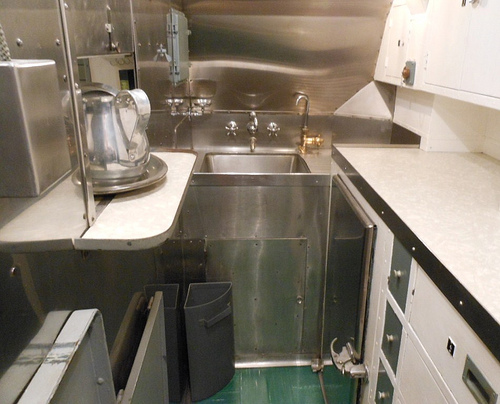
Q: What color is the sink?
A: Silver.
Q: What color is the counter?
A: White.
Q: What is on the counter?
A: Nothing.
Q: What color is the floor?
A: Green.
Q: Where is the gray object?
A: On the floor.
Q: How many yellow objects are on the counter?
A: 0.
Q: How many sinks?
A: 1.